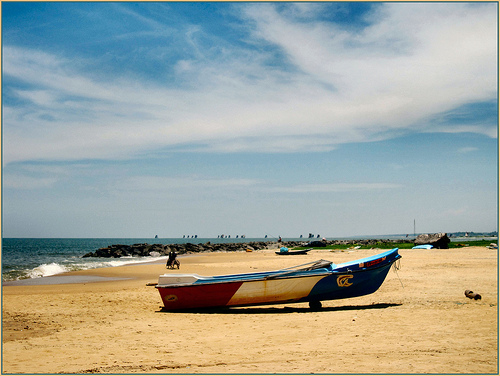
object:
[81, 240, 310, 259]
rocks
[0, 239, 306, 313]
jetty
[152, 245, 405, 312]
boat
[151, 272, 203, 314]
stern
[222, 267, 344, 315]
beam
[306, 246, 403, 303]
bow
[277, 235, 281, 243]
person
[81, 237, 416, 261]
breakwater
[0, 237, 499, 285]
water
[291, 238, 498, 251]
grass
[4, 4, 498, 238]
sky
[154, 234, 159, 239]
boats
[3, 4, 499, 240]
clouds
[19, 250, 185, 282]
waves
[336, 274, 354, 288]
logo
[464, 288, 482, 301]
log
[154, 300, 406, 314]
shadow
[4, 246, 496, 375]
sand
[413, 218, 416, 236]
mast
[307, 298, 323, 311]
log